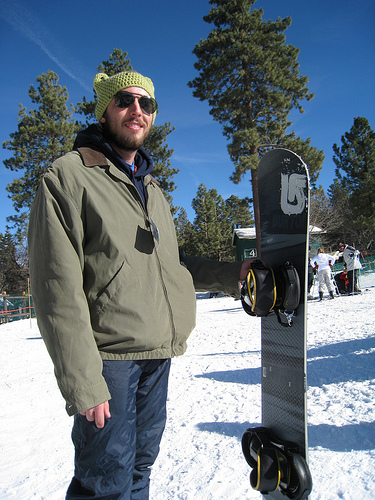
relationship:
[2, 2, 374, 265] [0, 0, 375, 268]
thin clouds in sky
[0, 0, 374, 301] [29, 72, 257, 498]
trees behind man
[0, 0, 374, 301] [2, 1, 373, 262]
trees have leaves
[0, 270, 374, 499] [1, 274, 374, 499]
snow on ground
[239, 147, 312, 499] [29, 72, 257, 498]
snowboard near man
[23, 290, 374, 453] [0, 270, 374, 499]
shadow on snow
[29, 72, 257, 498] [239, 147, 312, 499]
man holding snowboard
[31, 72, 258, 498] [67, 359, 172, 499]
man wearing pants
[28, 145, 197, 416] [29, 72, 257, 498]
jacket on man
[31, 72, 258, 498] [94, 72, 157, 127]
man wearing a hat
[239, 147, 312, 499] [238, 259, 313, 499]
snowboard has foot holders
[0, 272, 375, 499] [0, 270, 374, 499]
tracks on snow